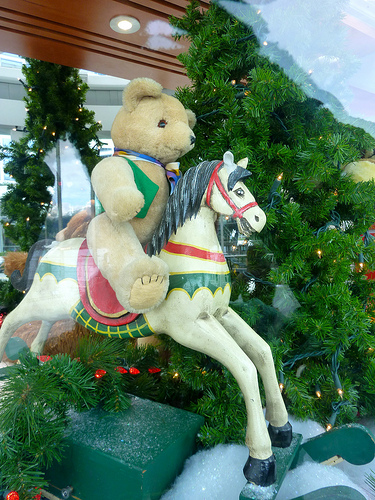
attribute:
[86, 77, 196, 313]
teddy bear — brown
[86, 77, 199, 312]
teddy — teddy bear, brown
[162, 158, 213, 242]
mane — black 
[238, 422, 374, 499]
base — green 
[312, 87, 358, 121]
ground — holiday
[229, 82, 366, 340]
tree — christmas tree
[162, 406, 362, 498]
snow — white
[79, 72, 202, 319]
bear — sitting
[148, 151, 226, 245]
mane — black, white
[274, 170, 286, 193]
lights — on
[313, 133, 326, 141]
lights — on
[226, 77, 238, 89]
lights — on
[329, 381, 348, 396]
lights — on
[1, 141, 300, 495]
horse — white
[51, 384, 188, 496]
box — green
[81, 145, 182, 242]
vest — green 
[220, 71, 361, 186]
greenery — lighted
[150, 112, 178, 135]
eyes — brown